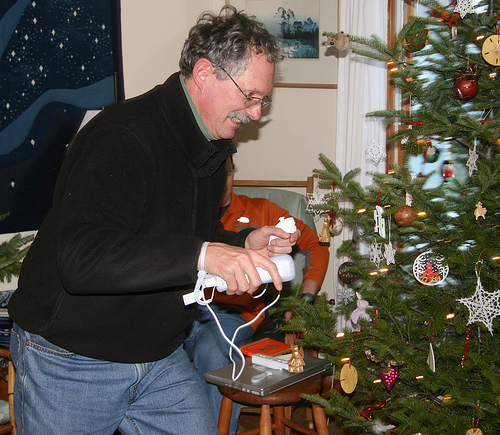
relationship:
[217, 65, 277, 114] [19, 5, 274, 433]
eyeglasses worn by man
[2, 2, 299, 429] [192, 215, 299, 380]
adult playing wii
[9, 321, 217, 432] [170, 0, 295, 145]
jeans worn by man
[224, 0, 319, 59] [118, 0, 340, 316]
image on wall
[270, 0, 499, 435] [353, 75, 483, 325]
christmas tree on tree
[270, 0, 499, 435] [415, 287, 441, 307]
christmas tree has leafs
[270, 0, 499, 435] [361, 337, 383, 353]
christmas tree has leafs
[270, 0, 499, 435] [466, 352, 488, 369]
christmas tree has leafs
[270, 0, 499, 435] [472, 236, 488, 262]
christmas tree has leafs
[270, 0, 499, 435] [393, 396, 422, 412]
christmas tree has leafs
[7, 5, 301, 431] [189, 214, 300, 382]
man playing video game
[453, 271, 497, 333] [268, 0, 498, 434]
snowflake ornament on christmas tree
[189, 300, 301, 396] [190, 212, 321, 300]
cord of controllers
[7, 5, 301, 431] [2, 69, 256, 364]
man wearing black sweater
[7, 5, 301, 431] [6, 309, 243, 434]
man wearing jeans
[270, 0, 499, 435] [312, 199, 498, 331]
christmas tree with ornaments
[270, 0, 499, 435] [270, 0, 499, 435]
christmas tree beside christmas tree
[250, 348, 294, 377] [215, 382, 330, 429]
controller on stool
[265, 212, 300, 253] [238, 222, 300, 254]
controller in hand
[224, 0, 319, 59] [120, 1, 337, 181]
image hanging on wall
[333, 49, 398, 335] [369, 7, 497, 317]
curtain next to window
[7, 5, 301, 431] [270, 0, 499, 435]
man standing next christmas tree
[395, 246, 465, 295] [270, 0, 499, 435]
ornament hanging on christmas tree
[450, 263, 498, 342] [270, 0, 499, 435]
ornament hanging on christmas tree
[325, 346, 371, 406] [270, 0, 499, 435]
ornament hanging on christmas tree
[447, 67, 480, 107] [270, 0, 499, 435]
ornament hanging on christmas tree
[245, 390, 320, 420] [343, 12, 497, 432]
stool next to tree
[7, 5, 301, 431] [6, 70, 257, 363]
man wearing sweater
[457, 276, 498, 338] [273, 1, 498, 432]
star on tree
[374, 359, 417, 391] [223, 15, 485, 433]
ornament on tree